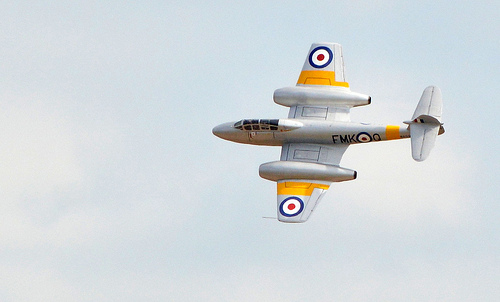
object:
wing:
[296, 42, 350, 86]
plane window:
[234, 118, 280, 132]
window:
[234, 118, 279, 131]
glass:
[233, 118, 279, 131]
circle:
[308, 45, 334, 70]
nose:
[212, 120, 248, 142]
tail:
[403, 85, 446, 162]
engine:
[273, 87, 373, 108]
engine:
[258, 159, 358, 183]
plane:
[212, 40, 447, 224]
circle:
[385, 123, 399, 140]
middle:
[274, 118, 384, 144]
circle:
[279, 196, 305, 218]